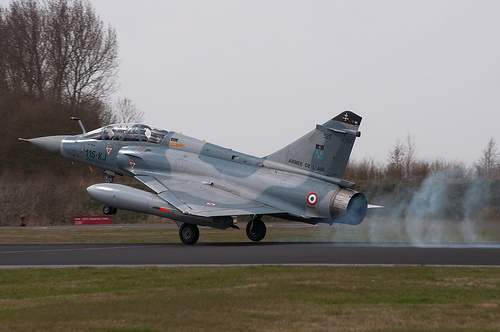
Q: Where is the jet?
A: On the runway.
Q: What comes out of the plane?
A: Exhaust.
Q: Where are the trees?
A: Behind the runway.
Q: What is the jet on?
A: Runway.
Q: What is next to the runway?
A: Grass.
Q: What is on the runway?
A: Military jet.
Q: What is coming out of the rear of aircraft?
A: Exhaust.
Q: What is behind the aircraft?
A: Large tree.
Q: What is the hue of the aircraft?
A: Gray and tan.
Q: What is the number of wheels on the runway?
A: Two.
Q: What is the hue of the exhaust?
A: White.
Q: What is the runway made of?
A: Asphalt.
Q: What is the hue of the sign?
A: Red.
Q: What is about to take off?
A: Military jet.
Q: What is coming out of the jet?
A: Smoke.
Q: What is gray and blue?
A: Plane.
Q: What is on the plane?
A: Window.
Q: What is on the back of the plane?
A: The tail.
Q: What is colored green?
A: Grass.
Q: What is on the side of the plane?
A: A wing.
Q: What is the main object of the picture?
A: Jet.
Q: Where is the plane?
A: Runway.